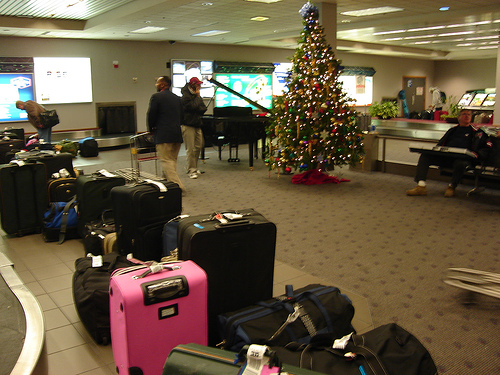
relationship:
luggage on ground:
[3, 126, 449, 373] [6, 166, 498, 368]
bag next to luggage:
[108, 176, 185, 258] [56, 171, 152, 230]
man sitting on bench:
[410, 108, 484, 200] [459, 128, 496, 195]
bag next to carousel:
[219, 278, 354, 350] [0, 246, 52, 371]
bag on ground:
[105, 258, 210, 374] [8, 246, 161, 372]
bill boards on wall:
[2, 59, 377, 114] [2, 36, 434, 163]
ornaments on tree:
[292, 56, 349, 138] [260, 0, 372, 181]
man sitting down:
[410, 108, 484, 200] [405, 108, 473, 193]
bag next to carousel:
[105, 258, 210, 374] [3, 251, 60, 372]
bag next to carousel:
[219, 278, 354, 350] [0, 236, 45, 372]